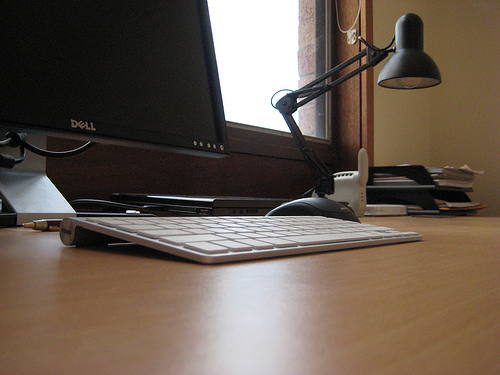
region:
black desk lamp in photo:
[301, 20, 456, 262]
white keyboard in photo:
[45, 219, 497, 276]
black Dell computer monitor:
[5, 5, 242, 187]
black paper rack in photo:
[351, 156, 498, 235]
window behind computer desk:
[25, 0, 385, 167]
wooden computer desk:
[7, 202, 327, 370]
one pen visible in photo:
[11, 213, 113, 261]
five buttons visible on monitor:
[151, 137, 267, 162]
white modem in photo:
[308, 160, 388, 228]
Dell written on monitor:
[54, 100, 151, 173]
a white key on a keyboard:
[192, 237, 227, 253]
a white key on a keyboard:
[218, 237, 249, 249]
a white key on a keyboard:
[239, 235, 269, 250]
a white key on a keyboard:
[263, 233, 288, 250]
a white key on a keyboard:
[291, 230, 366, 248]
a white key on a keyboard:
[361, 231, 380, 238]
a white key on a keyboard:
[161, 230, 222, 242]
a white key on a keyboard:
[141, 227, 181, 236]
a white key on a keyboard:
[118, 220, 158, 228]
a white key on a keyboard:
[100, 217, 130, 228]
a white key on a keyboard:
[222, 228, 243, 238]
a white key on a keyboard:
[240, 230, 263, 238]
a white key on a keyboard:
[263, 227, 278, 234]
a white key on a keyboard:
[140, 220, 184, 239]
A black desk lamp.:
[268, 26, 466, 194]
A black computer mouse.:
[288, 178, 358, 217]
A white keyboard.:
[62, 217, 405, 251]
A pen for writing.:
[18, 217, 59, 237]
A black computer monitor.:
[4, 1, 223, 199]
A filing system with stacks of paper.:
[362, 142, 486, 214]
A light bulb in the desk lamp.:
[372, 62, 441, 102]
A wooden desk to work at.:
[8, 204, 497, 373]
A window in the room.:
[213, 0, 325, 130]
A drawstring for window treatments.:
[337, 0, 370, 42]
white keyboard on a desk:
[57, 207, 425, 269]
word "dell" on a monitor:
[68, 117, 95, 136]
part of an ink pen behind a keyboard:
[15, 211, 65, 235]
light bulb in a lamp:
[394, 70, 425, 90]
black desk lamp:
[261, 11, 444, 225]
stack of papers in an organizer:
[336, 154, 491, 220]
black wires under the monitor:
[2, 131, 101, 171]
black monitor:
[2, 3, 237, 166]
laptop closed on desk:
[103, 187, 315, 222]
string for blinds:
[328, 2, 372, 41]